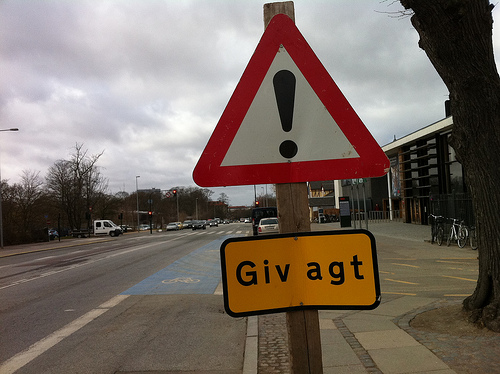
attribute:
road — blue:
[4, 234, 256, 370]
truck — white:
[65, 218, 122, 238]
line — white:
[4, 291, 157, 372]